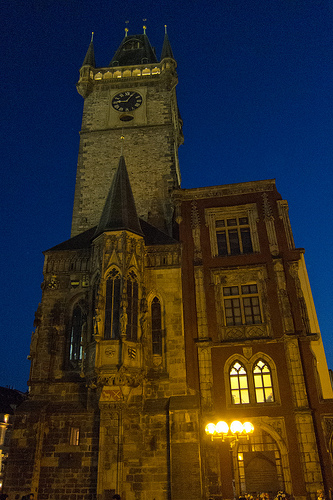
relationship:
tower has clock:
[76, 34, 183, 226] [108, 86, 145, 115]